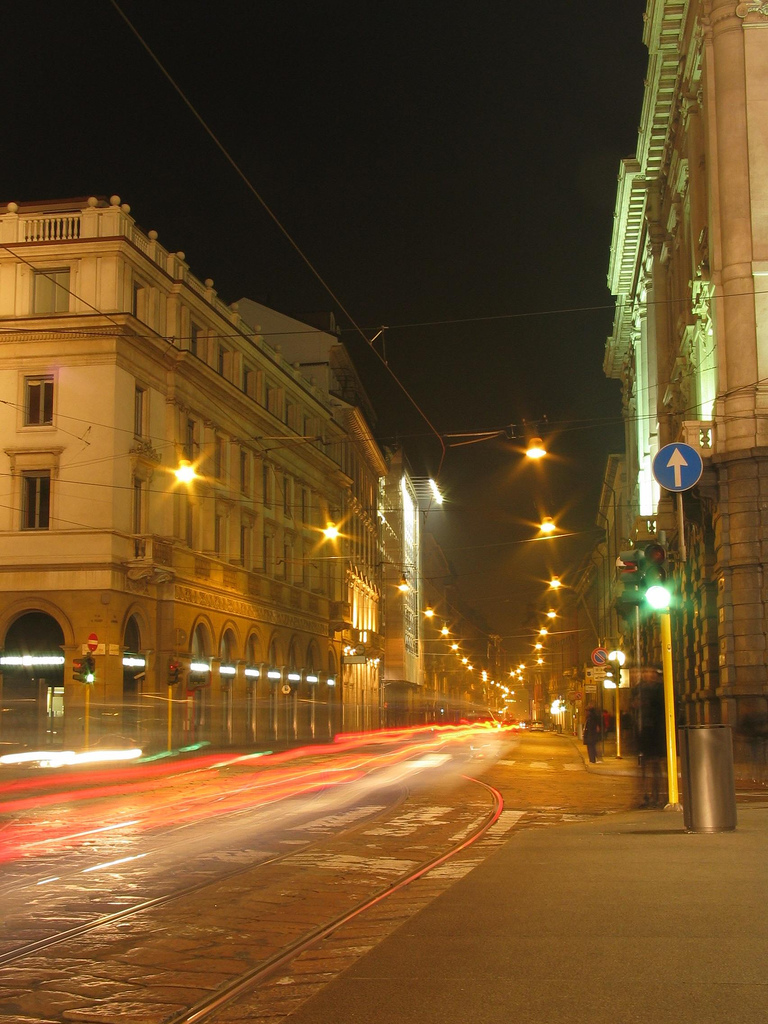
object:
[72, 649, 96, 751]
stoplight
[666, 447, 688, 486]
arrow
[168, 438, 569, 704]
arrow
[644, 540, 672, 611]
signals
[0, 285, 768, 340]
wires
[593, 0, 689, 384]
roof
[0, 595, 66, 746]
archways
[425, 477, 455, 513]
lights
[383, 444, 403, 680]
wall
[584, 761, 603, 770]
curb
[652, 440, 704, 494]
sign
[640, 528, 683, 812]
lamp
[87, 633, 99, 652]
sign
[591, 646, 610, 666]
sign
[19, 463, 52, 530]
window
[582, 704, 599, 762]
person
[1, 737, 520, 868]
blur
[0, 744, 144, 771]
light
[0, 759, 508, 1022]
tracks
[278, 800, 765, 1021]
sidewalk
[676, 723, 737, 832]
trashcan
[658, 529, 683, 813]
pole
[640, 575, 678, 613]
light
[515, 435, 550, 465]
lights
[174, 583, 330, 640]
sign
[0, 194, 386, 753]
building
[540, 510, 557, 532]
street lights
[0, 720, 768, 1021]
street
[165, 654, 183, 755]
street lamp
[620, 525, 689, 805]
traffic light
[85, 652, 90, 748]
pole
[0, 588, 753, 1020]
ahead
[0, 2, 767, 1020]
air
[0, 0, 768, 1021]
night